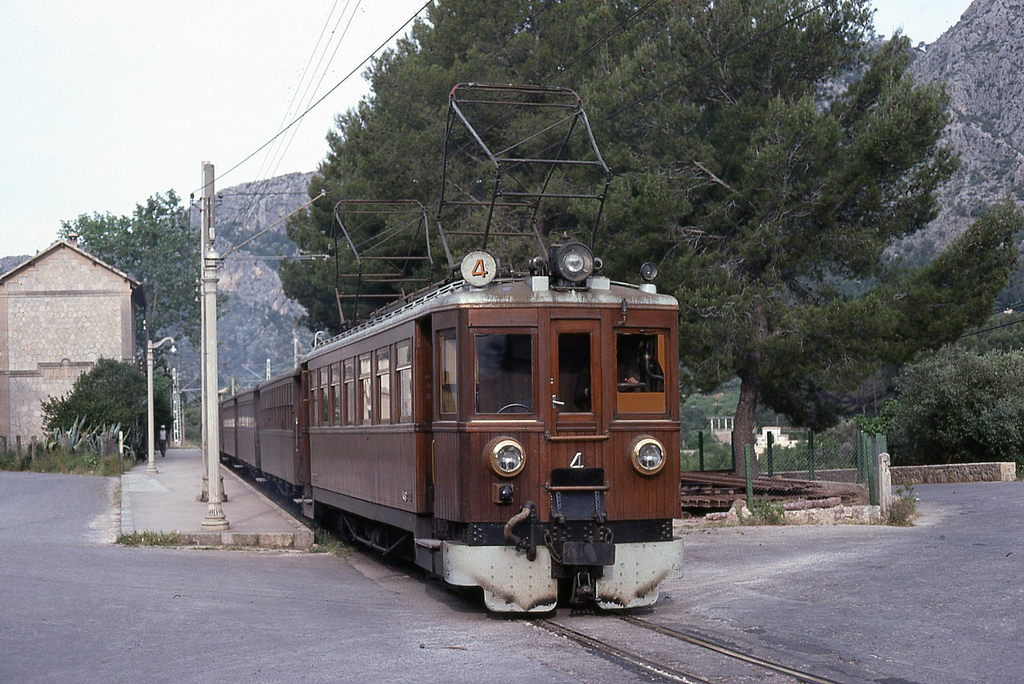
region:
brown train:
[239, 268, 701, 575]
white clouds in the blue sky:
[111, 10, 169, 65]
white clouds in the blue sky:
[231, 22, 295, 89]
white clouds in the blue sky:
[52, 72, 195, 174]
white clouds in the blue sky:
[137, 34, 218, 86]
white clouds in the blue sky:
[251, 66, 344, 144]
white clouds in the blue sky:
[23, 151, 93, 209]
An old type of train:
[219, 251, 679, 615]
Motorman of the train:
[622, 345, 658, 394]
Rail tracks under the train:
[524, 615, 838, 679]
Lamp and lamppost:
[203, 247, 222, 520]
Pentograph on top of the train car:
[437, 81, 611, 271]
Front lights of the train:
[493, 437, 665, 475]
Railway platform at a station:
[117, 444, 317, 550]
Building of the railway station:
[0, 236, 137, 459]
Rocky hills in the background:
[215, 1, 1021, 388]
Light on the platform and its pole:
[143, 334, 172, 461]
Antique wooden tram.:
[220, 83, 691, 622]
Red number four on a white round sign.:
[457, 247, 496, 285]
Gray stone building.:
[0, 240, 143, 459]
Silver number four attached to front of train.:
[563, 446, 595, 476]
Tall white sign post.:
[194, 224, 230, 539]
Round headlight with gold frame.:
[626, 435, 669, 478]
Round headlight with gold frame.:
[487, 437, 529, 479]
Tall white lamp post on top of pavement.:
[140, 318, 175, 477]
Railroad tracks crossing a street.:
[523, 606, 850, 682]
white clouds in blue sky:
[130, 35, 220, 118]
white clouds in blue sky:
[262, 2, 370, 110]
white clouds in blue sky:
[41, 25, 83, 63]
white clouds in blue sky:
[159, 54, 220, 109]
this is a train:
[142, 142, 754, 643]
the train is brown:
[230, 298, 725, 618]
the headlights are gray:
[445, 377, 769, 570]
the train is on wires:
[148, 35, 791, 365]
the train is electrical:
[370, 80, 685, 334]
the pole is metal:
[117, 171, 349, 450]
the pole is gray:
[125, 189, 247, 433]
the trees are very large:
[383, 6, 997, 396]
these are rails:
[632, 597, 756, 671]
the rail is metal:
[597, 604, 654, 640]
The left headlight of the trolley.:
[497, 436, 523, 475]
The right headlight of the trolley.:
[627, 433, 672, 476]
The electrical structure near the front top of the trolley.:
[431, 81, 615, 260]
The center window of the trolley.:
[556, 326, 588, 418]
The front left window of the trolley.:
[464, 326, 529, 409]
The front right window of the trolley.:
[627, 332, 667, 405]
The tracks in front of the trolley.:
[561, 594, 824, 681]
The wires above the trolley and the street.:
[176, 8, 439, 231]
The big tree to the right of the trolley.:
[284, 8, 1013, 411]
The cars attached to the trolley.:
[210, 379, 310, 493]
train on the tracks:
[177, 247, 890, 680]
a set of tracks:
[568, 590, 745, 677]